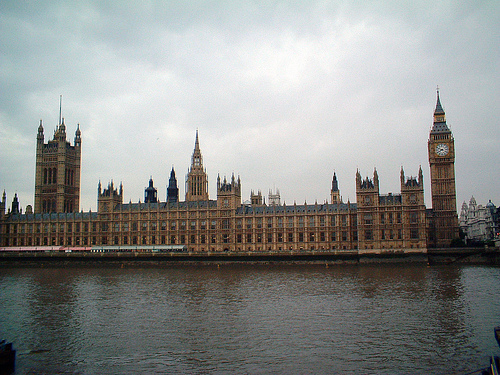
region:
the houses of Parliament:
[5, 82, 471, 261]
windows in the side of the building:
[7, 212, 459, 249]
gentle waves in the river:
[11, 261, 493, 373]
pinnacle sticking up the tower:
[57, 87, 63, 130]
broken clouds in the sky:
[6, 4, 498, 222]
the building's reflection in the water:
[2, 254, 494, 350]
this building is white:
[456, 191, 498, 245]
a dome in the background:
[484, 194, 496, 212]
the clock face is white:
[432, 142, 449, 160]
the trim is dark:
[423, 87, 455, 148]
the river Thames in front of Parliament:
[10, 259, 488, 362]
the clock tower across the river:
[427, 82, 461, 257]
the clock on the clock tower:
[431, 142, 451, 160]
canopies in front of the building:
[0, 244, 191, 256]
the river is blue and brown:
[3, 259, 494, 372]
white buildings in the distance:
[456, 189, 498, 251]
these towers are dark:
[137, 166, 178, 202]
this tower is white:
[263, 178, 281, 203]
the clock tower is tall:
[425, 81, 461, 255]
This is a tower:
[29, 103, 50, 163]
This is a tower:
[51, 115, 69, 145]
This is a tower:
[69, 118, 89, 154]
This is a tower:
[95, 175, 135, 215]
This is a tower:
[140, 167, 162, 212]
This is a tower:
[164, 153, 181, 210]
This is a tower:
[183, 120, 213, 212]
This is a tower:
[206, 158, 243, 218]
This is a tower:
[430, 93, 467, 221]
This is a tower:
[398, 153, 432, 223]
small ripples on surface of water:
[179, 295, 338, 357]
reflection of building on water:
[24, 265, 84, 339]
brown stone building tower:
[26, 97, 93, 207]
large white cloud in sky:
[41, 8, 153, 72]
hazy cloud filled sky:
[146, 0, 490, 82]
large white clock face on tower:
[432, 133, 454, 161]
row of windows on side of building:
[84, 215, 261, 237]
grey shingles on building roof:
[250, 200, 327, 214]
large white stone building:
[459, 195, 496, 239]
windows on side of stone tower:
[39, 159, 66, 191]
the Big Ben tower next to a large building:
[426, 93, 468, 241]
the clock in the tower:
[432, 139, 450, 157]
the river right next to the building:
[3, 262, 496, 373]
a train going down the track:
[1, 242, 194, 261]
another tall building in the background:
[29, 118, 80, 208]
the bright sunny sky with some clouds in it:
[4, 0, 496, 200]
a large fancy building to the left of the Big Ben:
[6, 175, 430, 252]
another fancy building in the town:
[460, 192, 497, 241]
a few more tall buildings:
[134, 135, 209, 205]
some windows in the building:
[182, 216, 357, 243]